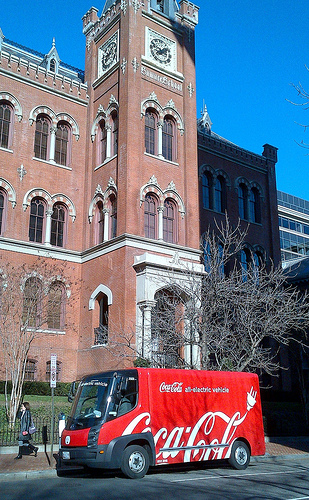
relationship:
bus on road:
[57, 367, 266, 478] [0, 439, 309, 500]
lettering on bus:
[130, 406, 237, 459] [57, 367, 266, 478]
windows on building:
[139, 184, 195, 241] [79, 5, 217, 372]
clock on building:
[144, 27, 177, 71] [0, 0, 284, 273]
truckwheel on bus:
[229, 441, 250, 470] [51, 370, 277, 490]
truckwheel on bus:
[121, 445, 150, 479] [51, 370, 277, 490]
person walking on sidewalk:
[14, 402, 38, 460] [0, 433, 308, 480]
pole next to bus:
[46, 354, 60, 470] [57, 367, 266, 478]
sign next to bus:
[46, 351, 61, 392] [57, 367, 266, 478]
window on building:
[141, 191, 157, 243] [1, 1, 307, 400]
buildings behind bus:
[0, 0, 292, 396] [57, 367, 266, 478]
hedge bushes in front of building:
[0, 380, 79, 395] [0, 0, 283, 384]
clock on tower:
[144, 27, 177, 76] [77, 0, 208, 380]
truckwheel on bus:
[121, 445, 150, 479] [57, 367, 266, 478]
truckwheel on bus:
[229, 441, 250, 470] [57, 367, 266, 478]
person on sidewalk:
[15, 402, 38, 459] [0, 425, 307, 481]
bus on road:
[57, 367, 266, 478] [19, 376, 295, 498]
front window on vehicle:
[71, 376, 103, 421] [55, 368, 267, 477]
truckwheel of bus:
[231, 441, 250, 467] [57, 367, 266, 478]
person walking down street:
[14, 402, 38, 460] [1, 435, 306, 498]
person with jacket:
[14, 402, 38, 460] [20, 409, 32, 439]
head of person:
[19, 401, 30, 412] [14, 402, 38, 460]